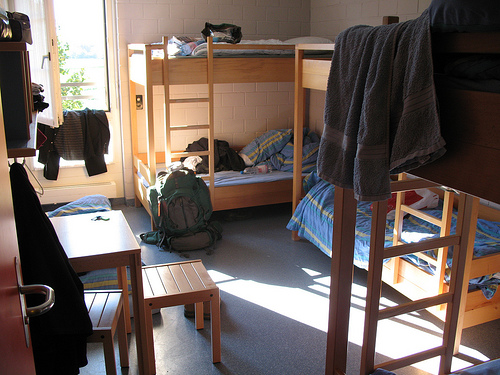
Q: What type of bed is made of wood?
A: Bunk bed.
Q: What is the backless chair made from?
A: Wood.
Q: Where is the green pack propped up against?
A: The bunk bed.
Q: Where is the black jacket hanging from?
A: The door.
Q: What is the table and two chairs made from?
A: Wood.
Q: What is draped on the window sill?
A: Shirts.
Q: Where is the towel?
A: On the nearest bed.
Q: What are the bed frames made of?
A: Wood.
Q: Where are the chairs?
A: Next to the table.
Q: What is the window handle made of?
A: Metal.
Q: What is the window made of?
A: Glass.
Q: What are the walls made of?
A: White bricks.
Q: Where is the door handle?
A: On the door.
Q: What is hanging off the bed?
A: A grey towel.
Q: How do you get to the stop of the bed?
A: Climb the four step ladder.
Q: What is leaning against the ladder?
A: A book bag.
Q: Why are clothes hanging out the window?
A: To dry off.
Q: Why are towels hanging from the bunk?
A: To dry off from being wet.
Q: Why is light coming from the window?
A: The sun is shining through.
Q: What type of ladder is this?
A: Wooden ladder.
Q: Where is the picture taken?
A: In the bedroom.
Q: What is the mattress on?
A: Bunk beds.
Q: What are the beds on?
A: Wood frames.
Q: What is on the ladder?
A: A towel.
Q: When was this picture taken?
A: In the afternoon.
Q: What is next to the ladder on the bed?
A: Backpack.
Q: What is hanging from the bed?
A: Ladders.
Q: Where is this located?
A: In a house.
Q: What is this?
A: A bedroom.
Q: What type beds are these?
A: Bunk beds.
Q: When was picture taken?
A: During daylight.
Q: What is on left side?
A: A t.v.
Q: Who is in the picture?
A: No one.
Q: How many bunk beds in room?
A: Two.